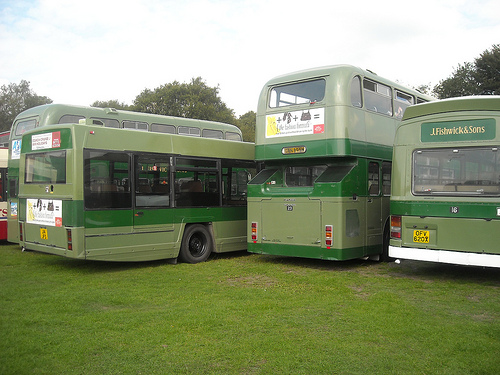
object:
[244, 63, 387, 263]
busses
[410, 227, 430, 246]
license plate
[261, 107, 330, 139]
sign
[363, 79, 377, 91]
windows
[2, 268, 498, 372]
grass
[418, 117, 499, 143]
sign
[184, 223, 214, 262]
tire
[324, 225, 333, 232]
taillights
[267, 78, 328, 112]
window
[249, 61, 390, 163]
levels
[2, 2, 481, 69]
sky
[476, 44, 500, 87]
trees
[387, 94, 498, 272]
vehicle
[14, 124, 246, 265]
bus